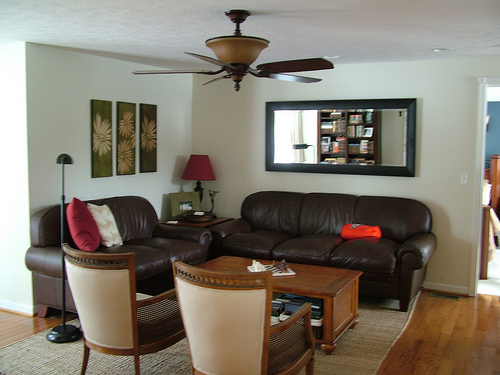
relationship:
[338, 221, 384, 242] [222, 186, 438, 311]
bag on couch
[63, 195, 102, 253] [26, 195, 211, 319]
pillow on couch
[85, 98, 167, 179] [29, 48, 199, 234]
artwork on wall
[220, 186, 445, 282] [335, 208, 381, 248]
sofa with bag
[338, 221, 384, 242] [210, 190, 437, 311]
bag on sofa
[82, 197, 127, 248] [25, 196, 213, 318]
pillow on couch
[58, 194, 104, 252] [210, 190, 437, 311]
pillow on sofa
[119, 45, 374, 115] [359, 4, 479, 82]
fan on ceiling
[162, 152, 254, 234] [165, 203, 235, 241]
lamp on night stand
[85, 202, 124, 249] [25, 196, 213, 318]
pillow on couch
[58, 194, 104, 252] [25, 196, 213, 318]
pillow on couch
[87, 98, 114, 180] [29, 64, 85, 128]
artwork on wall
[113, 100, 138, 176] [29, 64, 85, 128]
picture on wall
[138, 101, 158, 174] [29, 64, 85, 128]
picture on wall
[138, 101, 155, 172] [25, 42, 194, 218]
picture on wall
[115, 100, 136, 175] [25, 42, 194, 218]
picture on wall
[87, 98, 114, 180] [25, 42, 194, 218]
artwork on wall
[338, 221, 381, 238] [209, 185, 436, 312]
bag on sofa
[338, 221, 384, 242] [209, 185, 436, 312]
bag on sofa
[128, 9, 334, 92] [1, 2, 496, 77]
fan on ceiling